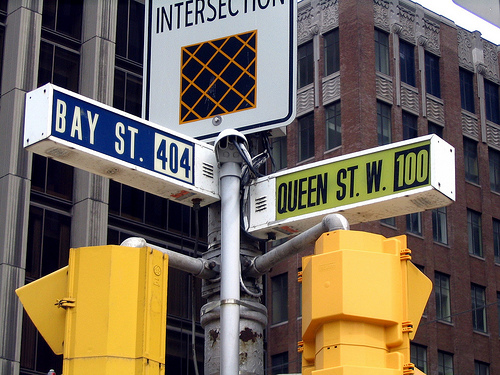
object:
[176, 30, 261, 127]
grid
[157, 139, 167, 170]
number 4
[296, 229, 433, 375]
light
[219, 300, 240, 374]
pipe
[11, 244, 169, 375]
light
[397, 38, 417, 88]
window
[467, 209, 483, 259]
window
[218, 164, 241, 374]
pole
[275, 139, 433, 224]
sign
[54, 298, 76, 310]
fastener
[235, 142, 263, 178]
wires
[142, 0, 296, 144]
sign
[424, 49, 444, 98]
window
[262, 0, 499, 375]
building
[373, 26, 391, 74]
window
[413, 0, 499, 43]
sky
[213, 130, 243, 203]
conduit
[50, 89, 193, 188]
sign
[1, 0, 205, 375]
building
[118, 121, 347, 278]
pipe fitting